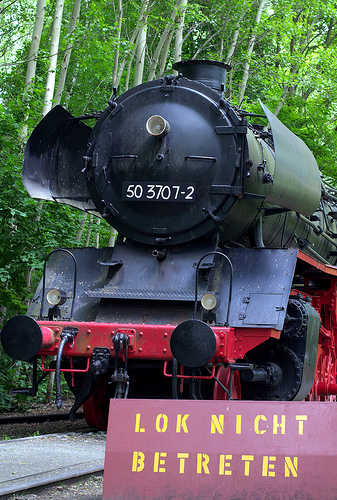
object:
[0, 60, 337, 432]
train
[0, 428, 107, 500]
tracks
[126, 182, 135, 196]
number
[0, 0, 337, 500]
photo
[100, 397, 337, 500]
sign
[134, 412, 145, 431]
lettering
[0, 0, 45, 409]
trees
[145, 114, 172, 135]
light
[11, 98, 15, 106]
leaves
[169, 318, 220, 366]
object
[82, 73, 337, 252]
tube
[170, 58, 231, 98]
smokestack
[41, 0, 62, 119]
trunk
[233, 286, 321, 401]
engine